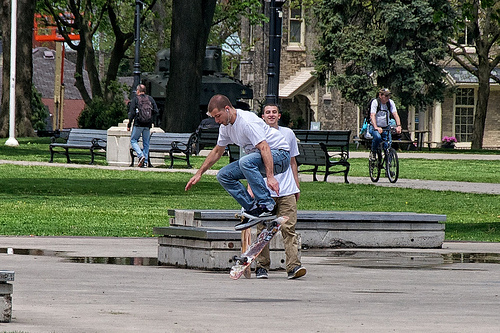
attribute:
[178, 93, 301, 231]
skateboarder — performing, crouched, jumping, in air, trick, skateboarding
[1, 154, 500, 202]
sidewalk — cement, gray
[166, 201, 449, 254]
benches — concrete, stone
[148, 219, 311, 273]
benches — concrete, stone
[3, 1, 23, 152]
post — light, white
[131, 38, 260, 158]
tank — metal, grey, dark, large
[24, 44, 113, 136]
building — brick, red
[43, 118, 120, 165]
bench — green, wood, metal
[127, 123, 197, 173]
bench — metal, wood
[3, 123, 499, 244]
lawn — green, manicured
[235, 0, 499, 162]
building — stone, large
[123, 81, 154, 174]
man — balding, walking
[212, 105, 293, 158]
t-shirt — white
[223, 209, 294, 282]
skateboard — upside down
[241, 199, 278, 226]
shoes — black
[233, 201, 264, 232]
shoes — black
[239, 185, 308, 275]
pants — brown